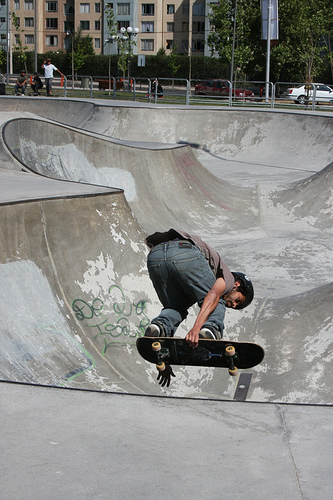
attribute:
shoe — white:
[143, 325, 162, 339]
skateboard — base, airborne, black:
[134, 336, 264, 368]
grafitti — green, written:
[72, 286, 151, 352]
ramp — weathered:
[0, 111, 250, 400]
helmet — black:
[232, 270, 257, 311]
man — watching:
[41, 57, 64, 95]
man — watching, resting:
[31, 72, 43, 95]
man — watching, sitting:
[13, 69, 31, 97]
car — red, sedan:
[197, 78, 258, 99]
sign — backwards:
[262, 1, 277, 40]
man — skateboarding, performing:
[146, 233, 255, 340]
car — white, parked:
[287, 83, 332, 106]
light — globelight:
[118, 26, 143, 40]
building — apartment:
[2, 1, 223, 57]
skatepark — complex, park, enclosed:
[1, 94, 332, 478]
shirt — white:
[41, 65, 58, 80]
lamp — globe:
[120, 26, 128, 35]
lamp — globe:
[127, 24, 134, 38]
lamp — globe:
[133, 24, 140, 36]